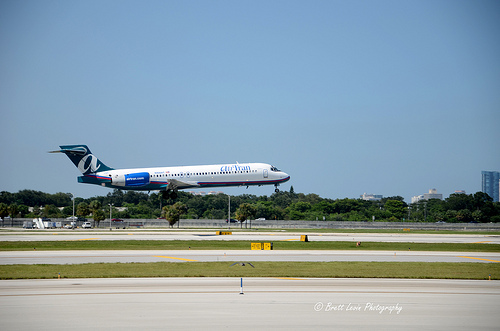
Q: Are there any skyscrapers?
A: Yes, there is a skyscraper.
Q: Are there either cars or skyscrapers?
A: Yes, there is a skyscraper.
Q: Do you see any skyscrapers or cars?
A: Yes, there is a skyscraper.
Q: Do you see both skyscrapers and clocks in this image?
A: No, there is a skyscraper but no clocks.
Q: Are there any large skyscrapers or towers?
A: Yes, there is a large skyscraper.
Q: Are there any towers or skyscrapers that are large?
A: Yes, the skyscraper is large.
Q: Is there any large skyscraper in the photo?
A: Yes, there is a large skyscraper.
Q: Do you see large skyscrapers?
A: Yes, there is a large skyscraper.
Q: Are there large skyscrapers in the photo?
A: Yes, there is a large skyscraper.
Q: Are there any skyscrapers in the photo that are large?
A: Yes, there is a skyscraper that is large.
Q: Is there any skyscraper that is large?
A: Yes, there is a skyscraper that is large.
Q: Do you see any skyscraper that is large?
A: Yes, there is a skyscraper that is large.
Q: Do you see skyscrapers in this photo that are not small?
A: Yes, there is a large skyscraper.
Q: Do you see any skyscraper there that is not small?
A: Yes, there is a large skyscraper.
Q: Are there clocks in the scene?
A: No, there are no clocks.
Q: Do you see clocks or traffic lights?
A: No, there are no clocks or traffic lights.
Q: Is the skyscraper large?
A: Yes, the skyscraper is large.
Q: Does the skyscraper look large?
A: Yes, the skyscraper is large.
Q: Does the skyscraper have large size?
A: Yes, the skyscraper is large.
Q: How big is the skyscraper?
A: The skyscraper is large.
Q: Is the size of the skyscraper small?
A: No, the skyscraper is large.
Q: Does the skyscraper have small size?
A: No, the skyscraper is large.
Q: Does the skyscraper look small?
A: No, the skyscraper is large.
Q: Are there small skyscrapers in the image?
A: No, there is a skyscraper but it is large.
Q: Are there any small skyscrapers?
A: No, there is a skyscraper but it is large.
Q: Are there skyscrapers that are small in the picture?
A: No, there is a skyscraper but it is large.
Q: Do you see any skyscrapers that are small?
A: No, there is a skyscraper but it is large.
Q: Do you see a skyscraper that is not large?
A: No, there is a skyscraper but it is large.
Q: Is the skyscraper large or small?
A: The skyscraper is large.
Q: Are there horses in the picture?
A: No, there are no horses.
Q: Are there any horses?
A: No, there are no horses.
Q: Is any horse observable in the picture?
A: No, there are no horses.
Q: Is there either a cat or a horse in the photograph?
A: No, there are no horses or cats.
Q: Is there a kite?
A: No, there are no kites.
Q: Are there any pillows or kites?
A: No, there are no kites or pillows.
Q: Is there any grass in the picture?
A: Yes, there is grass.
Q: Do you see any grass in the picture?
A: Yes, there is grass.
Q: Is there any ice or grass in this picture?
A: Yes, there is grass.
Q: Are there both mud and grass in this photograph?
A: No, there is grass but no mud.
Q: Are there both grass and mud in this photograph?
A: No, there is grass but no mud.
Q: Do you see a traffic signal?
A: No, there are no traffic lights.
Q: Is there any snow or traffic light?
A: No, there are no traffic lights or snow.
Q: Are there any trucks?
A: No, there are no trucks.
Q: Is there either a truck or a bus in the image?
A: No, there are no trucks or buses.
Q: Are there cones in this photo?
A: No, there are no cones.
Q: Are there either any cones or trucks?
A: No, there are no cones or trucks.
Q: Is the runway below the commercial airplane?
A: Yes, the runway is below the plane.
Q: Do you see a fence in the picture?
A: Yes, there is a fence.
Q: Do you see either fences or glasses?
A: Yes, there is a fence.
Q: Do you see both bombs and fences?
A: No, there is a fence but no bombs.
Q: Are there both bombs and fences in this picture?
A: No, there is a fence but no bombs.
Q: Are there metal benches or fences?
A: Yes, there is a metal fence.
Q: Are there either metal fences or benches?
A: Yes, there is a metal fence.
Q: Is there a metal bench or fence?
A: Yes, there is a metal fence.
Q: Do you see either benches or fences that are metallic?
A: Yes, the fence is metallic.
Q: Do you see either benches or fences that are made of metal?
A: Yes, the fence is made of metal.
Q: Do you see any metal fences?
A: Yes, there is a metal fence.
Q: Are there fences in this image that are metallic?
A: Yes, there is a metal fence.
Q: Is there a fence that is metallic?
A: Yes, there is a fence that is metallic.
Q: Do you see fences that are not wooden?
A: Yes, there is a metallic fence.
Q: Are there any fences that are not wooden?
A: Yes, there is a metallic fence.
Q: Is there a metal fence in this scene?
A: Yes, there is a fence that is made of metal.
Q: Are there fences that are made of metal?
A: Yes, there is a fence that is made of metal.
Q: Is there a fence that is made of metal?
A: Yes, there is a fence that is made of metal.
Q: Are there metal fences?
A: Yes, there is a fence that is made of metal.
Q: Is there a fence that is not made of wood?
A: Yes, there is a fence that is made of metal.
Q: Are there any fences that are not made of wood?
A: Yes, there is a fence that is made of metal.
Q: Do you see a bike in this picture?
A: No, there are no bikes.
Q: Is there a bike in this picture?
A: No, there are no bikes.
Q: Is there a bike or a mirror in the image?
A: No, there are no bikes or mirrors.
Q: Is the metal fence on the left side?
A: Yes, the fence is on the left of the image.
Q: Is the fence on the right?
A: No, the fence is on the left of the image.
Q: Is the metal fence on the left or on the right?
A: The fence is on the left of the image.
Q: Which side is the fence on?
A: The fence is on the left of the image.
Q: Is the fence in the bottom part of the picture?
A: Yes, the fence is in the bottom of the image.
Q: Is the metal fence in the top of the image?
A: No, the fence is in the bottom of the image.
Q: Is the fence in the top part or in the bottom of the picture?
A: The fence is in the bottom of the image.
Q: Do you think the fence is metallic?
A: Yes, the fence is metallic.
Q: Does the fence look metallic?
A: Yes, the fence is metallic.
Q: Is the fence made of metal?
A: Yes, the fence is made of metal.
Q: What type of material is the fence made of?
A: The fence is made of metal.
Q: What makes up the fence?
A: The fence is made of metal.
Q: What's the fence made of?
A: The fence is made of metal.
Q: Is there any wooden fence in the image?
A: No, there is a fence but it is metallic.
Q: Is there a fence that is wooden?
A: No, there is a fence but it is metallic.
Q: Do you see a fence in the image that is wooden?
A: No, there is a fence but it is metallic.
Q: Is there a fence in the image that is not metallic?
A: No, there is a fence but it is metallic.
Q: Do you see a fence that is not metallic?
A: No, there is a fence but it is metallic.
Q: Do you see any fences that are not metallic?
A: No, there is a fence but it is metallic.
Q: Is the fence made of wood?
A: No, the fence is made of metal.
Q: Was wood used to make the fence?
A: No, the fence is made of metal.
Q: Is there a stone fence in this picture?
A: No, there is a fence but it is made of metal.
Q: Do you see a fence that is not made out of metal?
A: No, there is a fence but it is made of metal.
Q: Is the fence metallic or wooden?
A: The fence is metallic.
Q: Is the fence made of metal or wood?
A: The fence is made of metal.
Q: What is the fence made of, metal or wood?
A: The fence is made of metal.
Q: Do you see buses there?
A: No, there are no buses.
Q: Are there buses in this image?
A: No, there are no buses.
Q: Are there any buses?
A: No, there are no buses.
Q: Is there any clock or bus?
A: No, there are no buses or clocks.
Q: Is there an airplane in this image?
A: Yes, there is an airplane.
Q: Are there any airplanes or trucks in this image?
A: Yes, there is an airplane.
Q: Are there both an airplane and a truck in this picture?
A: No, there is an airplane but no trucks.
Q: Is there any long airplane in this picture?
A: Yes, there is a long airplane.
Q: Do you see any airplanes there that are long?
A: Yes, there is an airplane that is long.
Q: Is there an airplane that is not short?
A: Yes, there is a long airplane.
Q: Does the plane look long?
A: Yes, the plane is long.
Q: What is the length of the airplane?
A: The airplane is long.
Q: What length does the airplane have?
A: The airplane has long length.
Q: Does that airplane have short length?
A: No, the airplane is long.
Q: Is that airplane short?
A: No, the airplane is long.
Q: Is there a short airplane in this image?
A: No, there is an airplane but it is long.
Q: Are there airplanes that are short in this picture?
A: No, there is an airplane but it is long.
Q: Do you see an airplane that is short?
A: No, there is an airplane but it is long.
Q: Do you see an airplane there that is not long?
A: No, there is an airplane but it is long.